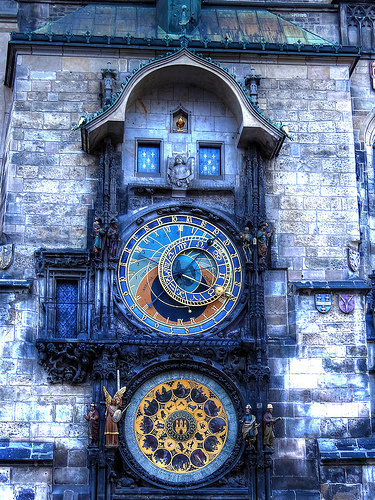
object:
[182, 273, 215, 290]
hands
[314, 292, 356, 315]
couple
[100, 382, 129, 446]
statue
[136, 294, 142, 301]
tick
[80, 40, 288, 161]
arch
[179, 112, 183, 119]
statuette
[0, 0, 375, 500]
wall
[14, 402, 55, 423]
brick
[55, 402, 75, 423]
brick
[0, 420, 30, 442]
brick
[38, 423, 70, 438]
brick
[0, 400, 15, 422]
brick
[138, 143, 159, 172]
stained glass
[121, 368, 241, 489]
colorful clock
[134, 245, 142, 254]
tick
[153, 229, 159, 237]
tick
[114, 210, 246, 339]
clock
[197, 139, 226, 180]
window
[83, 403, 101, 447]
statuettes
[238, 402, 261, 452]
statuettes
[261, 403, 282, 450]
statuettes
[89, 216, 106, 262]
statuettes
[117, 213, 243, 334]
mechanical calendar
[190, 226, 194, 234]
tick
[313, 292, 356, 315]
crest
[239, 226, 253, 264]
art figure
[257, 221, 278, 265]
art figure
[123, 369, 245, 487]
mechanical calendar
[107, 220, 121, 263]
statuettes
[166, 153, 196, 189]
statuette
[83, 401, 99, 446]
statues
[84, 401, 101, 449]
man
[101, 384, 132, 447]
angel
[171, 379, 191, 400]
ornaments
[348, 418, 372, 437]
bricks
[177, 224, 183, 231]
tick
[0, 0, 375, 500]
building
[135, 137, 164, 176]
window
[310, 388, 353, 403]
brick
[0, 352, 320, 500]
shadow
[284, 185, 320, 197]
bricks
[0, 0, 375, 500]
outside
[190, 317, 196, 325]
tick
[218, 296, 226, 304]
tick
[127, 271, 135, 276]
tick